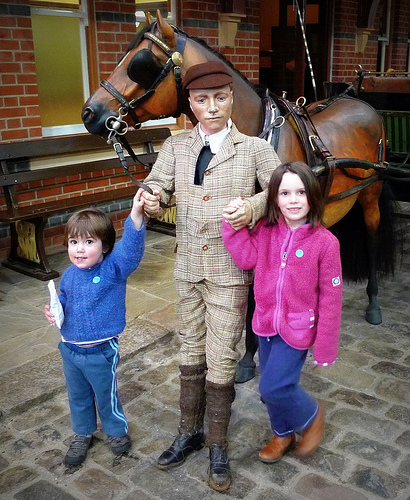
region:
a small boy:
[28, 193, 182, 481]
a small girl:
[198, 140, 379, 470]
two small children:
[12, 173, 368, 379]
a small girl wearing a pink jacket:
[238, 160, 366, 348]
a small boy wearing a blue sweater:
[36, 197, 153, 366]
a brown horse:
[68, 1, 406, 211]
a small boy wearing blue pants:
[33, 202, 146, 455]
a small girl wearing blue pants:
[247, 134, 320, 452]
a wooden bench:
[3, 110, 208, 257]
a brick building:
[4, 7, 358, 198]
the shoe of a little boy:
[63, 424, 89, 464]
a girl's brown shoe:
[296, 406, 325, 460]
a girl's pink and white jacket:
[217, 212, 345, 366]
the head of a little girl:
[259, 159, 328, 232]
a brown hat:
[180, 58, 235, 91]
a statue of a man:
[140, 59, 280, 491]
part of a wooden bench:
[1, 125, 172, 281]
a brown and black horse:
[76, 8, 408, 323]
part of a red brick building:
[176, 0, 263, 80]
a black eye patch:
[118, 50, 166, 85]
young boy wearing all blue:
[43, 185, 145, 466]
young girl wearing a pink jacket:
[219, 159, 343, 465]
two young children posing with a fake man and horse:
[0, 1, 408, 498]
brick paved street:
[342, 324, 406, 497]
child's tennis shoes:
[61, 435, 134, 468]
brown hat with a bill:
[179, 59, 233, 91]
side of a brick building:
[0, 18, 40, 135]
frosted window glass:
[27, 13, 83, 126]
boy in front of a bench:
[0, 126, 192, 465]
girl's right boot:
[256, 428, 296, 463]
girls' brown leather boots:
[253, 417, 342, 464]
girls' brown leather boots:
[265, 409, 303, 466]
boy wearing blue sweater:
[38, 210, 182, 388]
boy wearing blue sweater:
[63, 197, 113, 345]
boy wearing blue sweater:
[66, 229, 226, 484]